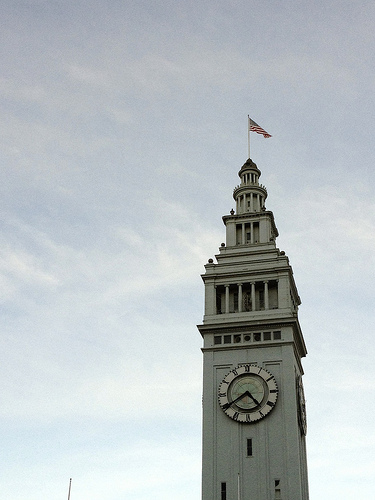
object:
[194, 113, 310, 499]
tower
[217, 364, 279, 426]
clock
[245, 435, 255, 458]
window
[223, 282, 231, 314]
column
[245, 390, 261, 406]
hand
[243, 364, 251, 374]
roman numeral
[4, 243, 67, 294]
cloud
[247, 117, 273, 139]
flag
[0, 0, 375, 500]
sky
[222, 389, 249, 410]
hand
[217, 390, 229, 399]
roman numeral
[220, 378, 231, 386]
roman numeral